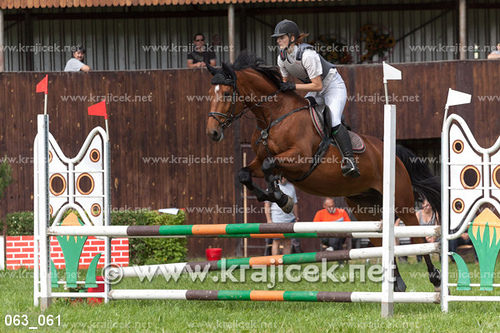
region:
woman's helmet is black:
[255, 16, 317, 54]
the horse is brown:
[195, 47, 472, 227]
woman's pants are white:
[321, 71, 357, 136]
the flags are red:
[19, 48, 134, 150]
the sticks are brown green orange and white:
[70, 207, 447, 329]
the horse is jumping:
[190, 21, 446, 252]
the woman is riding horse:
[182, 3, 483, 287]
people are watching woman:
[22, 7, 230, 104]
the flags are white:
[370, 57, 490, 131]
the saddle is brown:
[302, 105, 375, 164]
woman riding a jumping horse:
[215, 21, 415, 220]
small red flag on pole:
[37, 76, 46, 115]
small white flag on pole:
[380, 61, 400, 99]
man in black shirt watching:
[186, 35, 212, 71]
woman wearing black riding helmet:
[277, 20, 353, 161]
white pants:
[321, 67, 343, 126]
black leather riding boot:
[333, 125, 350, 176]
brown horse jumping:
[210, 58, 416, 225]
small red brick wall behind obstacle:
[1, 232, 128, 269]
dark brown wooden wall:
[4, 73, 497, 230]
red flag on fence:
[31, 68, 62, 115]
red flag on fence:
[81, 92, 117, 127]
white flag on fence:
[371, 58, 406, 103]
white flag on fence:
[433, 89, 475, 115]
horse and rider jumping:
[212, 18, 436, 248]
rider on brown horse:
[259, 7, 355, 165]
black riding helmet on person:
[266, 19, 303, 43]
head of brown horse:
[190, 48, 259, 142]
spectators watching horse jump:
[43, 32, 217, 74]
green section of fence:
[158, 219, 192, 238]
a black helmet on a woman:
[268, 15, 308, 39]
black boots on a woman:
[332, 119, 360, 181]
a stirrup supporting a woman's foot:
[332, 145, 361, 178]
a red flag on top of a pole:
[32, 72, 60, 114]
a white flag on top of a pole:
[376, 58, 413, 108]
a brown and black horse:
[194, 46, 443, 286]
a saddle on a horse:
[300, 92, 353, 130]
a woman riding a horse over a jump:
[188, 15, 457, 294]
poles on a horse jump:
[28, 217, 463, 308]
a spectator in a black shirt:
[185, 30, 221, 71]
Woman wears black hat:
[265, 13, 302, 40]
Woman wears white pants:
[331, 76, 346, 117]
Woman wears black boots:
[337, 125, 358, 153]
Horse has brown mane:
[231, 51, 265, 71]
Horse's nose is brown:
[202, 123, 229, 145]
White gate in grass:
[26, 124, 121, 219]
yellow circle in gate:
[76, 172, 98, 198]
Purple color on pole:
[126, 217, 161, 244]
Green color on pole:
[158, 219, 193, 241]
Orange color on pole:
[189, 223, 227, 234]